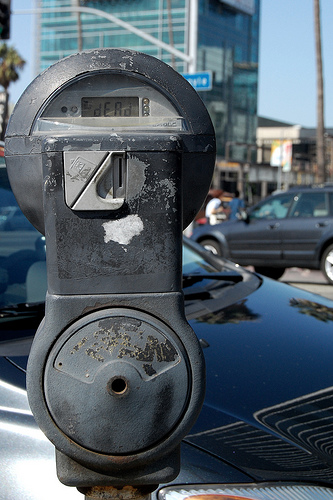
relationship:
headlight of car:
[156, 481, 331, 498] [167, 130, 332, 270]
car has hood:
[0, 156, 332, 498] [1, 271, 332, 498]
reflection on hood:
[180, 368, 331, 493] [1, 271, 332, 498]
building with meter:
[31, 0, 263, 164] [3, 48, 216, 498]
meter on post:
[3, 48, 216, 498] [77, 487, 159, 499]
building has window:
[215, 158, 316, 221] [219, 171, 237, 191]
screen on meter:
[80, 94, 140, 117] [3, 48, 216, 498]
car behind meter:
[0, 156, 332, 498] [3, 48, 216, 498]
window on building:
[161, 31, 184, 43] [31, 0, 263, 164]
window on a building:
[219, 171, 238, 195] [49, 8, 256, 197]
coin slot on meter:
[113, 154, 123, 189] [3, 48, 216, 498]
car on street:
[186, 186, 331, 285] [246, 264, 331, 300]